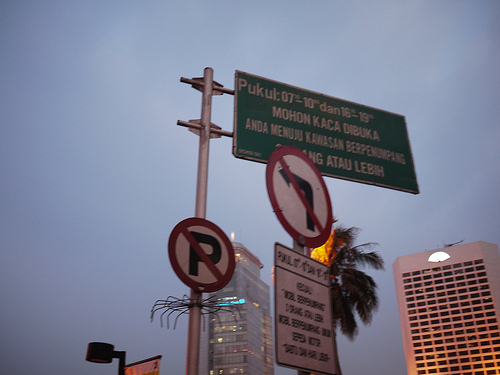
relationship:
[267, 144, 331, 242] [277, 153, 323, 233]
sign says no left turns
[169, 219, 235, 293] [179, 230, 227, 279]
sign for no parking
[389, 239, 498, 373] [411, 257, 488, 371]
building lit windows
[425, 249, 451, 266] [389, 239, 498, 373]
logo on building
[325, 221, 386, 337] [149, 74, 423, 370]
palm tree behind signs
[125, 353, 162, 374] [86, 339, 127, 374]
banner on streetlight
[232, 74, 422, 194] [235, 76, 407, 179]
sign with white letters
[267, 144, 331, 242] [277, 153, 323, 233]
sign for no left turns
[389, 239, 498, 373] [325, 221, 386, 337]
building beyond palm tree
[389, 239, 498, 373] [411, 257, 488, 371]
building with windows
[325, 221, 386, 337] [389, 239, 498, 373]
palm tree in front of building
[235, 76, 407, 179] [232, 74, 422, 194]
white letters on a green sign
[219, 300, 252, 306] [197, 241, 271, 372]
light on building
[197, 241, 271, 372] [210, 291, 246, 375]
building has windows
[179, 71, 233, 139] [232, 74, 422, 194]
bracket to hold sign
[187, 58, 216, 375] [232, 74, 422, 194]
pole holding sign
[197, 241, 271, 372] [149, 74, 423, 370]
building behind signs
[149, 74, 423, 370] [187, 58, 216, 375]
signs on a pole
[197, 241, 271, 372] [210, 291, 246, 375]
building with windows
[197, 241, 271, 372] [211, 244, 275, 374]
building has lights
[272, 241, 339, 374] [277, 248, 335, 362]
sign has black writing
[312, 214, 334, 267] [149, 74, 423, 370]
light behind signs